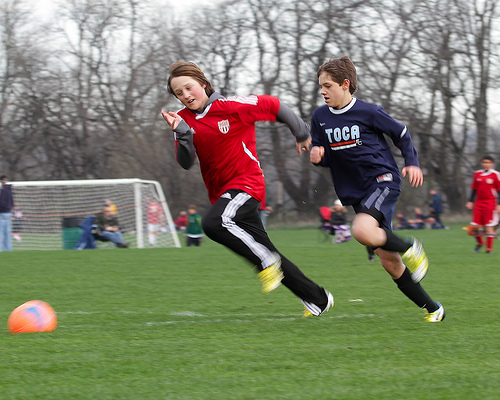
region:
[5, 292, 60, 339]
moving soccer ball on the pitch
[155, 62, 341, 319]
boy soccer player chasing after ball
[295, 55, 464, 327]
boy in blue jersey running after soccer ball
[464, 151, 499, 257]
member of soccer team on the field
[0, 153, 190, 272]
soccer net waiting for a goal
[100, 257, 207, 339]
green grass of a soccer field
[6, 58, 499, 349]
boys of opposing teams run after soccer ball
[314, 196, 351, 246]
fan watches a soccer match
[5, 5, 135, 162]
trees in a park during the fall/winter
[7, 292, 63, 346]
orange soccer ball in motion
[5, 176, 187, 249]
a white soccer goal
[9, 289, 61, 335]
a large orange ball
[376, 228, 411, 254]
a boy's black sock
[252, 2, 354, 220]
a tall gray tree branch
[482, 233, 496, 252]
a boy's red sock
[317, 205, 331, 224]
part of a red chair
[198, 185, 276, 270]
the leg of a boy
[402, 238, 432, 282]
a boy's soccer shoe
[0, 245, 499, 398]
a section of green grass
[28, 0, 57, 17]
part of a white sky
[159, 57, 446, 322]
Two boys running after soccer ball.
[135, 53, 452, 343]
boys playing with a ball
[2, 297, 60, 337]
the ball is orange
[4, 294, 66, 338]
the ball is flat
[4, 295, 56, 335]
the ball has a blue spot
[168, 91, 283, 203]
the shirt is red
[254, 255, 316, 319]
his shoes are yellow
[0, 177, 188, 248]
a person kneeling in the goal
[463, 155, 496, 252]
a person wearing red and running up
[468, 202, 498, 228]
his shorts are red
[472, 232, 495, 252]
his socks are red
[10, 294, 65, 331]
orange and blue soccer ball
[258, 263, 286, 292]
yellow and white sneakers on feet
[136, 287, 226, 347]
white lines on grass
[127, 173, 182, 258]
edge of white goal post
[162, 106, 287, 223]
red and white shirt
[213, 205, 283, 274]
white stripes on black pants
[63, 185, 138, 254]
man standing in the goal post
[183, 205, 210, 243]
man wearing green and white shirt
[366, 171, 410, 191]
logo on blue shirt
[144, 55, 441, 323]
players running on the field